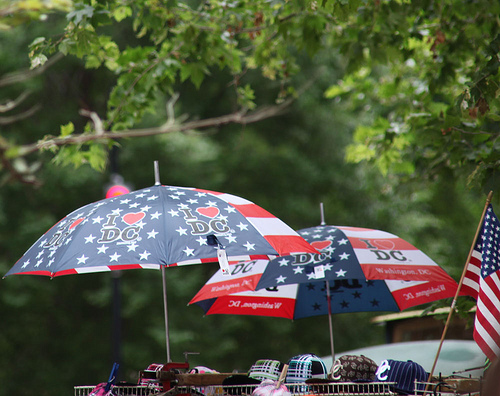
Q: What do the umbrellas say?
A: I love DC.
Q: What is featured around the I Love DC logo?
A: Blue and white stars.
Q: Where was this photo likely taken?
A: Washington D.C.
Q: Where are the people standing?
A: Under the umbrellas.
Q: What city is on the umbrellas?
A: D.C.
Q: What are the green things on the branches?
A: Leaves.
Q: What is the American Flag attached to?
A: Stick.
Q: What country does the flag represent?
A: USA.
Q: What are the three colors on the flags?
A: Red, white and blue.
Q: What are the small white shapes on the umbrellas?
A: Stars.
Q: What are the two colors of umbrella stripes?
A: Red and white.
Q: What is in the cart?
A: Caps.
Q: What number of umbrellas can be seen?
A: Two.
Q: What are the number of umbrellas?
A: 2.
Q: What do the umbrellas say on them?
A: I (heart) DC.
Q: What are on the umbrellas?
A: Stars and stripes.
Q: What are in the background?
A: Trees.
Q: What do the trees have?
A: Green leaves.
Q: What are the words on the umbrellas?
A: I love DC.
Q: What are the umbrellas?
A: Red, white, and blue.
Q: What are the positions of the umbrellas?
A: Upright.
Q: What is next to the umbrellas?
A: An American flag.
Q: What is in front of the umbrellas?
A: Hats are in front of umbrellas.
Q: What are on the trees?
A: There are leaves on the tree.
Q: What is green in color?
A: The trees leaves.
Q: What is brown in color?
A: The flags handle.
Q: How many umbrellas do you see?
A: 2.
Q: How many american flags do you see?
A: 1.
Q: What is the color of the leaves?
A: Green.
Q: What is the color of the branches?
A: Brown.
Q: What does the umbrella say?
A: I love DC.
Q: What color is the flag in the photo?
A: Red, white, and blue.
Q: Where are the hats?
A: Below the umbrellas.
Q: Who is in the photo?
A: No one.